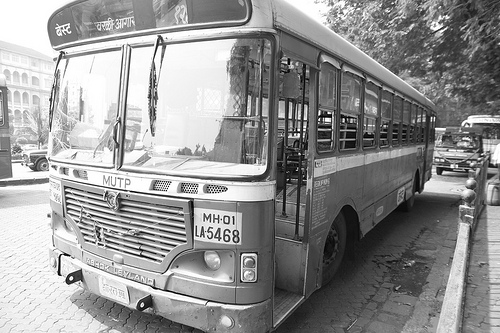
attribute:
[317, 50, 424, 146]
windows — many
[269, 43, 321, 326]
door — opened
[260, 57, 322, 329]
door bus — open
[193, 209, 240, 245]
sign — white, black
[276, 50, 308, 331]
door — open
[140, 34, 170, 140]
wiper — pointed down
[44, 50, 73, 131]
wiper — pointed down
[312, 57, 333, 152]
window — open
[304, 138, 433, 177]
stripe — white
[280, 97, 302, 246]
poles — black